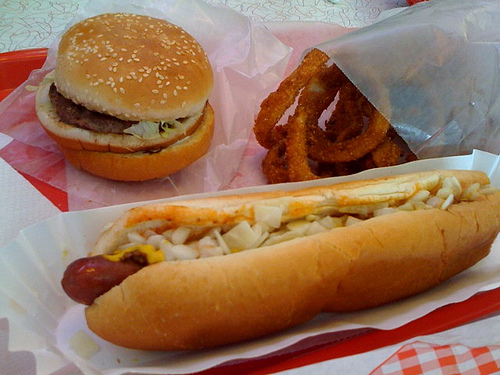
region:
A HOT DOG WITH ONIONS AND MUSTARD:
[49, 153, 498, 361]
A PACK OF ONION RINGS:
[248, 6, 489, 191]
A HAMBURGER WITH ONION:
[31, 6, 231, 182]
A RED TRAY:
[6, 33, 490, 368]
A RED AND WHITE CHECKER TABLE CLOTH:
[380, 336, 495, 371]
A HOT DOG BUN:
[65, 163, 496, 363]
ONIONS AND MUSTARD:
[114, 220, 256, 267]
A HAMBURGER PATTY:
[41, 71, 155, 142]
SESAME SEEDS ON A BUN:
[68, 20, 210, 108]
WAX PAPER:
[6, 0, 285, 209]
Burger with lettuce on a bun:
[45, 12, 219, 187]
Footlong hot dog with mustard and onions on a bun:
[70, 196, 497, 285]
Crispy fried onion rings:
[265, 46, 415, 173]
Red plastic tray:
[4, 38, 40, 80]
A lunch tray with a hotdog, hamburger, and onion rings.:
[3, 2, 498, 359]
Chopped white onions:
[167, 234, 229, 251]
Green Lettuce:
[129, 123, 160, 140]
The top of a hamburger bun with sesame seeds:
[80, 27, 190, 99]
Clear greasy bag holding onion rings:
[307, 22, 499, 164]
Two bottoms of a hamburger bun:
[40, 110, 215, 173]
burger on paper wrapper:
[6, 5, 291, 203]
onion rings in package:
[255, 0, 499, 171]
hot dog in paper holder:
[15, 141, 499, 333]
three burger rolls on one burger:
[21, 5, 248, 185]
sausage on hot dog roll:
[38, 215, 498, 327]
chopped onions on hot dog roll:
[111, 153, 498, 253]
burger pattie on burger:
[35, 52, 224, 149]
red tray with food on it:
[7, 3, 498, 373]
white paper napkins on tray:
[0, 112, 78, 374]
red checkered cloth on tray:
[371, 309, 498, 374]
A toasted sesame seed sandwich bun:
[68, 10, 199, 127]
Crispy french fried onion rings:
[253, 47, 400, 182]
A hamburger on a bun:
[39, 87, 204, 145]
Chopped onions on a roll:
[132, 210, 400, 261]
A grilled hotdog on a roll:
[46, 219, 144, 316]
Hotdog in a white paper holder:
[26, 144, 497, 367]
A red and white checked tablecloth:
[330, 324, 499, 373]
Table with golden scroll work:
[5, 0, 105, 49]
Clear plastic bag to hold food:
[288, 1, 496, 137]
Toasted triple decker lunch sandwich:
[37, 19, 262, 192]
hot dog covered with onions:
[59, 167, 499, 351]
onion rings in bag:
[251, 0, 499, 180]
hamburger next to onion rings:
[29, 12, 217, 182]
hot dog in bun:
[61, 169, 499, 356]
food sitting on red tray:
[2, 18, 494, 372]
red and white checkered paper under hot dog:
[366, 342, 498, 373]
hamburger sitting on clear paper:
[0, 0, 295, 212]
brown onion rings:
[251, 46, 413, 183]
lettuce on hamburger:
[33, 12, 217, 184]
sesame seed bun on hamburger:
[51, 9, 216, 123]